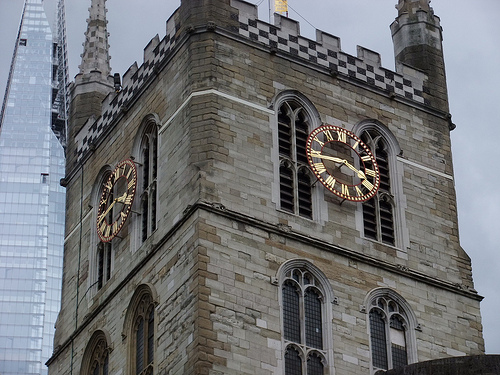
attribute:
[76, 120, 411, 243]
clock — golden, lit, round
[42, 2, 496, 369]
building — arched, large, stone, tall, checkered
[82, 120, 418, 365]
windows — arched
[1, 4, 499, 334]
sky — cloudy, blue